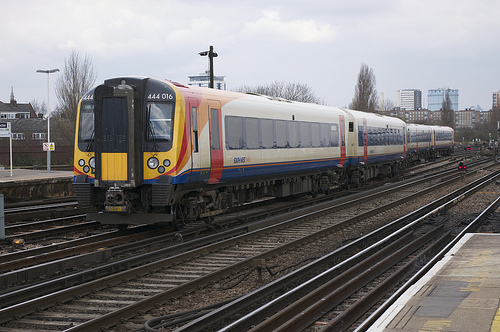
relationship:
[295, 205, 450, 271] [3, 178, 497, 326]
tracks part of railway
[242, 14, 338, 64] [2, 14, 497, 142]
clouds in sky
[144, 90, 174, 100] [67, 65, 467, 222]
number on train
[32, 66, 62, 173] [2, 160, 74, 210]
street lamp on railway platform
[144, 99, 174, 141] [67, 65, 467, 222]
windshield on train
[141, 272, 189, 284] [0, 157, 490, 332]
sleeper between railway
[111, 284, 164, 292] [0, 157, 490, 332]
sleeper between railway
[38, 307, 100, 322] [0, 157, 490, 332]
sleeper between railway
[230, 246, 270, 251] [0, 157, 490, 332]
sleeper between railway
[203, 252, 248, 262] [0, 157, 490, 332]
sleeper between railway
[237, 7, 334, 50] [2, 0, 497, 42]
cloud in sky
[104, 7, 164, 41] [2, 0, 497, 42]
cloud in sky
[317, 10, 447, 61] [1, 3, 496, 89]
clouds in sky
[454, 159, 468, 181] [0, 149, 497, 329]
lights between tracks